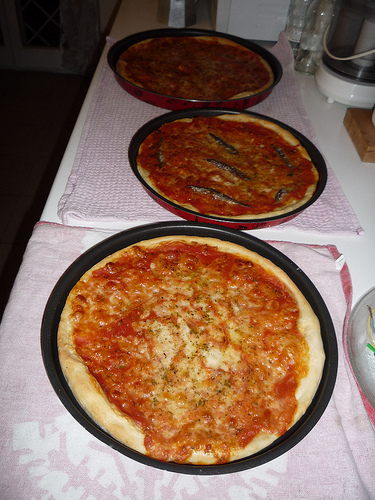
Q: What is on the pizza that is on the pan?
A: The anchovies are on the pizza.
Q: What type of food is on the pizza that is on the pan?
A: The food is anchovies.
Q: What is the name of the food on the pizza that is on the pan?
A: The food is anchovies.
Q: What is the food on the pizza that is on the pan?
A: The food is anchovies.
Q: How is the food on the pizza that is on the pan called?
A: The food is anchovies.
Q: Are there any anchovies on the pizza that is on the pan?
A: Yes, there are anchovies on the pizza.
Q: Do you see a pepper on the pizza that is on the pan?
A: No, there are anchovies on the pizza.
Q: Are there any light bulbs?
A: No, there are no light bulbs.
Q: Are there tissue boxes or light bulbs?
A: No, there are no light bulbs or tissue boxes.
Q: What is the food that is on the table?
A: The food is pizzas.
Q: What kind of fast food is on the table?
A: The food is pizzas.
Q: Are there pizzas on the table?
A: Yes, there are pizzas on the table.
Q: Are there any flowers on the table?
A: No, there are pizzas on the table.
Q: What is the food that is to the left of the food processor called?
A: The food is pizzas.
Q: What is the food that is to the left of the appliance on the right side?
A: The food is pizzas.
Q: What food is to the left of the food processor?
A: The food is pizzas.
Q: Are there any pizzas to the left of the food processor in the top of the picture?
A: Yes, there are pizzas to the left of the food processor.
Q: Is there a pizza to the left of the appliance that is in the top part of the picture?
A: Yes, there are pizzas to the left of the food processor.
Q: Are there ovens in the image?
A: No, there are no ovens.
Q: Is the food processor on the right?
A: Yes, the food processor is on the right of the image.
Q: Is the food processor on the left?
A: No, the food processor is on the right of the image.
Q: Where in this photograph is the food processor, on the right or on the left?
A: The food processor is on the right of the image.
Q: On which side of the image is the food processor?
A: The food processor is on the right of the image.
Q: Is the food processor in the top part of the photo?
A: Yes, the food processor is in the top of the image.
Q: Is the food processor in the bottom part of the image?
A: No, the food processor is in the top of the image.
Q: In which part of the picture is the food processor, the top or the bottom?
A: The food processor is in the top of the image.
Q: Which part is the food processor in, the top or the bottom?
A: The food processor is in the top of the image.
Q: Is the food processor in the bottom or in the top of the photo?
A: The food processor is in the top of the image.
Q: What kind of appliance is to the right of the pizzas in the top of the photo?
A: The appliance is a food processor.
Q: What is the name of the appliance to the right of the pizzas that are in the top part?
A: The appliance is a food processor.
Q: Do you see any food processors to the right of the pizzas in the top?
A: Yes, there is a food processor to the right of the pizzas.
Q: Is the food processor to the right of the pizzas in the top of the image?
A: Yes, the food processor is to the right of the pizzas.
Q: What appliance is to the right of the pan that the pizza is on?
A: The appliance is a food processor.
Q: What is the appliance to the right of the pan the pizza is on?
A: The appliance is a food processor.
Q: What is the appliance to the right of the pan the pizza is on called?
A: The appliance is a food processor.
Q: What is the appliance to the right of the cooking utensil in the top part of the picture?
A: The appliance is a food processor.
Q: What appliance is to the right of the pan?
A: The appliance is a food processor.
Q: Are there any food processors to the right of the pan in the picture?
A: Yes, there is a food processor to the right of the pan.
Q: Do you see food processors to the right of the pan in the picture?
A: Yes, there is a food processor to the right of the pan.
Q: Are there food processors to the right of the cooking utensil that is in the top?
A: Yes, there is a food processor to the right of the pan.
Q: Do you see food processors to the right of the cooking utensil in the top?
A: Yes, there is a food processor to the right of the pan.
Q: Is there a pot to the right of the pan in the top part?
A: No, there is a food processor to the right of the pan.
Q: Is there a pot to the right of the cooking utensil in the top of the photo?
A: No, there is a food processor to the right of the pan.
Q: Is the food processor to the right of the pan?
A: Yes, the food processor is to the right of the pan.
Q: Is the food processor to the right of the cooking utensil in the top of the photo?
A: Yes, the food processor is to the right of the pan.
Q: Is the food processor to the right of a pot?
A: No, the food processor is to the right of the pan.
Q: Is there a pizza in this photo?
A: Yes, there is a pizza.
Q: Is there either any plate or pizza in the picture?
A: Yes, there is a pizza.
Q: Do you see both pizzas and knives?
A: No, there is a pizza but no knives.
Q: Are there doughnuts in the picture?
A: No, there are no doughnuts.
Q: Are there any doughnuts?
A: No, there are no doughnuts.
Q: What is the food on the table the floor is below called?
A: The food is a pizza.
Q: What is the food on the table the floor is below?
A: The food is a pizza.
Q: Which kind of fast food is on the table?
A: The food is a pizza.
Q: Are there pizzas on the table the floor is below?
A: Yes, there is a pizza on the table.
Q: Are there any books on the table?
A: No, there is a pizza on the table.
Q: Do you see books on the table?
A: No, there is a pizza on the table.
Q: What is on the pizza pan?
A: The pizza is on the pizza pan.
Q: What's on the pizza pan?
A: The pizza is on the pizza pan.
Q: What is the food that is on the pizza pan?
A: The food is a pizza.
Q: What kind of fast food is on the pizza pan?
A: The food is a pizza.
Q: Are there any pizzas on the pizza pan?
A: Yes, there is a pizza on the pizza pan.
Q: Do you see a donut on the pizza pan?
A: No, there is a pizza on the pizza pan.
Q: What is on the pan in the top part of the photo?
A: The pizza is on the pan.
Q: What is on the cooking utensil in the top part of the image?
A: The pizza is on the pan.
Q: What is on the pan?
A: The pizza is on the pan.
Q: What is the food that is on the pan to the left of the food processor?
A: The food is a pizza.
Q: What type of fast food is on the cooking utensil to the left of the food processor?
A: The food is a pizza.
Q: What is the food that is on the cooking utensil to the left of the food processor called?
A: The food is a pizza.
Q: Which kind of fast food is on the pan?
A: The food is a pizza.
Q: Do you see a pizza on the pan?
A: Yes, there is a pizza on the pan.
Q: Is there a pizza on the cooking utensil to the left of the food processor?
A: Yes, there is a pizza on the pan.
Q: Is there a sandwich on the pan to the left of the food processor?
A: No, there is a pizza on the pan.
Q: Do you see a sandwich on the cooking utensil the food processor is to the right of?
A: No, there is a pizza on the pan.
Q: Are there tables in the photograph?
A: Yes, there is a table.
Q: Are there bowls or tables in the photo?
A: Yes, there is a table.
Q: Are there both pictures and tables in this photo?
A: No, there is a table but no pictures.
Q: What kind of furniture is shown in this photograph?
A: The furniture is a table.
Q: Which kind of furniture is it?
A: The piece of furniture is a table.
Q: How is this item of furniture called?
A: That is a table.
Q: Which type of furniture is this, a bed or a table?
A: That is a table.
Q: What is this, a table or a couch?
A: This is a table.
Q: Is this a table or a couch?
A: This is a table.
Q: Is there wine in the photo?
A: No, there is no wine.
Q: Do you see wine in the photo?
A: No, there is no wine.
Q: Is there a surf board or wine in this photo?
A: No, there are no wine or surfboards.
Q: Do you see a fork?
A: No, there are no forks.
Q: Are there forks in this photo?
A: No, there are no forks.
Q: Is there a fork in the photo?
A: No, there are no forks.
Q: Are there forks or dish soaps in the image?
A: No, there are no forks or dish soaps.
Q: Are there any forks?
A: No, there are no forks.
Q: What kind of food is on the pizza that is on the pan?
A: The food is anchovies.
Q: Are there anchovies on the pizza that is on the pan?
A: Yes, there are anchovies on the pizza.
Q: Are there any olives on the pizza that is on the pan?
A: No, there are anchovies on the pizza.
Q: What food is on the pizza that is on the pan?
A: The food is anchovies.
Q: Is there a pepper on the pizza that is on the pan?
A: No, there are anchovies on the pizza.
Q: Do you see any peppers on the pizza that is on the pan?
A: No, there are anchovies on the pizza.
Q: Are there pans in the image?
A: Yes, there is a pan.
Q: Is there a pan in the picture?
A: Yes, there is a pan.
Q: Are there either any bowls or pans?
A: Yes, there is a pan.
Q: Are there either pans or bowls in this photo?
A: Yes, there is a pan.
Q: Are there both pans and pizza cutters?
A: No, there is a pan but no pizza cutters.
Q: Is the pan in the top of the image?
A: Yes, the pan is in the top of the image.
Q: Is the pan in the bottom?
A: No, the pan is in the top of the image.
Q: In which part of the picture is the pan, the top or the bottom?
A: The pan is in the top of the image.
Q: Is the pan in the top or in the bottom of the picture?
A: The pan is in the top of the image.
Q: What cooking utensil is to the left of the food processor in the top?
A: The cooking utensil is a pan.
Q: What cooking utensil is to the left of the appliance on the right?
A: The cooking utensil is a pan.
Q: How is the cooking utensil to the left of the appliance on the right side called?
A: The cooking utensil is a pan.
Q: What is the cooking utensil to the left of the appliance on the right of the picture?
A: The cooking utensil is a pan.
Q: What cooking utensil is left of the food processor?
A: The cooking utensil is a pan.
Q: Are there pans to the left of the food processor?
A: Yes, there is a pan to the left of the food processor.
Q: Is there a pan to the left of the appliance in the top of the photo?
A: Yes, there is a pan to the left of the food processor.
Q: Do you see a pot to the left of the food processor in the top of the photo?
A: No, there is a pan to the left of the food processor.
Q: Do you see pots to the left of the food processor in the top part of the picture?
A: No, there is a pan to the left of the food processor.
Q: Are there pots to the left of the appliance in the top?
A: No, there is a pan to the left of the food processor.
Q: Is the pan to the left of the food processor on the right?
A: Yes, the pan is to the left of the food processor.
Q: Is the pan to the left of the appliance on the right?
A: Yes, the pan is to the left of the food processor.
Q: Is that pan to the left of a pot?
A: No, the pan is to the left of the food processor.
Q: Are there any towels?
A: Yes, there is a towel.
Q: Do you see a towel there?
A: Yes, there is a towel.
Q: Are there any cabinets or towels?
A: Yes, there is a towel.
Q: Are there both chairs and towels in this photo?
A: No, there is a towel but no chairs.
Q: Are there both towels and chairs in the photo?
A: No, there is a towel but no chairs.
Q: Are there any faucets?
A: No, there are no faucets.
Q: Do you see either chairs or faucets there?
A: No, there are no faucets or chairs.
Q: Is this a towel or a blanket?
A: This is a towel.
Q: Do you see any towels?
A: Yes, there is a towel.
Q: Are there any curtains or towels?
A: Yes, there is a towel.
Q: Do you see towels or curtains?
A: Yes, there is a towel.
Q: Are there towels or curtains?
A: Yes, there is a towel.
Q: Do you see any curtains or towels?
A: Yes, there is a towel.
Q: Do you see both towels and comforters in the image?
A: No, there is a towel but no comforters.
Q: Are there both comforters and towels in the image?
A: No, there is a towel but no comforters.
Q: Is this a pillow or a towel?
A: This is a towel.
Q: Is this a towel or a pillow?
A: This is a towel.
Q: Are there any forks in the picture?
A: No, there are no forks.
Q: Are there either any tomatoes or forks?
A: No, there are no forks or tomatoes.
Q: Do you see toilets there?
A: No, there are no toilets.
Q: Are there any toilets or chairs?
A: No, there are no toilets or chairs.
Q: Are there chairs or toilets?
A: No, there are no toilets or chairs.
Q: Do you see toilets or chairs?
A: No, there are no toilets or chairs.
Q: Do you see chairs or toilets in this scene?
A: No, there are no toilets or chairs.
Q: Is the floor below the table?
A: Yes, the floor is below the table.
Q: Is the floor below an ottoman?
A: No, the floor is below the table.